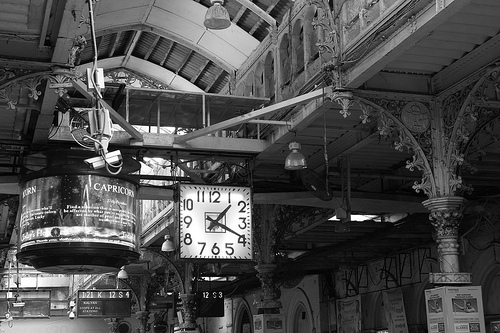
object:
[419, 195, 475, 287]
pillar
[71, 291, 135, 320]
billboard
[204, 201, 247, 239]
hands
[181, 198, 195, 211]
number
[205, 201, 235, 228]
hand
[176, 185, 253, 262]
clock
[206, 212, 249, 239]
hand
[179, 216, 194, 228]
nine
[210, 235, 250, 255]
number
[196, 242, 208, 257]
number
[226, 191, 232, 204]
number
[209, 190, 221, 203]
number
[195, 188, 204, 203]
number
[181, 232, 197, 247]
number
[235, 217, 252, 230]
number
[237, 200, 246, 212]
number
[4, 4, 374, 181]
ceiling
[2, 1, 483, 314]
photo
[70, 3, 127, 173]
camera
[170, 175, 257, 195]
frame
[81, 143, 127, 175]
camera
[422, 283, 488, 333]
posters